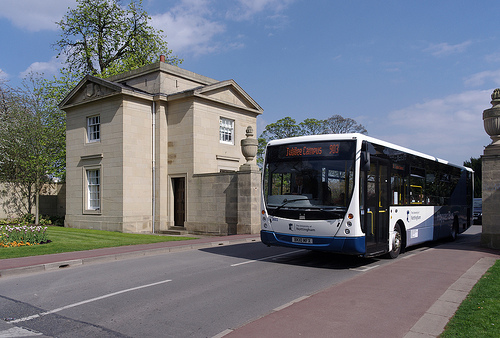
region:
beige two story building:
[56, 48, 263, 240]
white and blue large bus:
[255, 129, 477, 264]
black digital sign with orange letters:
[264, 136, 359, 162]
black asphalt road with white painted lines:
[1, 227, 480, 336]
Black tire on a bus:
[384, 220, 411, 263]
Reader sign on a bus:
[263, 136, 364, 166]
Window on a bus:
[266, 147, 356, 225]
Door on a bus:
[360, 148, 397, 259]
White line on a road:
[2, 253, 174, 325]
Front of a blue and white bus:
[258, 130, 377, 266]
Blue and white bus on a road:
[251, 114, 483, 259]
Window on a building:
[73, 160, 107, 222]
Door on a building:
[162, 170, 193, 237]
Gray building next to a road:
[51, 62, 263, 246]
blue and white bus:
[265, 132, 457, 267]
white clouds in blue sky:
[295, 23, 326, 48]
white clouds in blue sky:
[390, 32, 447, 72]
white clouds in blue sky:
[400, 89, 455, 136]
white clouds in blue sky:
[194, 18, 235, 45]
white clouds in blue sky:
[245, 15, 319, 60]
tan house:
[67, 72, 241, 254]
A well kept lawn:
[1, 229, 194, 256]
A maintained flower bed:
[1, 226, 53, 248]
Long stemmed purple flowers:
[4, 221, 50, 244]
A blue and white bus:
[264, 139, 476, 255]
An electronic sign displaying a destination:
[264, 141, 363, 161]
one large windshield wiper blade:
[275, 196, 343, 216]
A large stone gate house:
[62, 66, 257, 244]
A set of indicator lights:
[340, 208, 355, 235]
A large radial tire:
[387, 221, 407, 259]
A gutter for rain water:
[150, 101, 159, 238]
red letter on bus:
[283, 144, 290, 156]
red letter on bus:
[287, 148, 292, 156]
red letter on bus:
[316, 145, 323, 156]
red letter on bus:
[313, 145, 320, 157]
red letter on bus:
[303, 145, 311, 155]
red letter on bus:
[301, 145, 306, 155]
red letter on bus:
[297, 146, 302, 156]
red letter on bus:
[292, 144, 297, 154]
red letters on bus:
[285, 145, 325, 155]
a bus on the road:
[251, 127, 477, 266]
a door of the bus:
[362, 150, 394, 255]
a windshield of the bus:
[260, 153, 358, 224]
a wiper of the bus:
[268, 193, 325, 215]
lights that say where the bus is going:
[282, 137, 345, 158]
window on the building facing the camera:
[81, 115, 104, 134]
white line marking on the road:
[35, 269, 180, 323]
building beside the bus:
[70, 66, 238, 236]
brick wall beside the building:
[202, 174, 261, 218]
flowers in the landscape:
[9, 224, 41, 245]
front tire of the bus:
[393, 221, 408, 254]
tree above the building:
[58, 1, 144, 54]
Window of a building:
[218, 117, 234, 144]